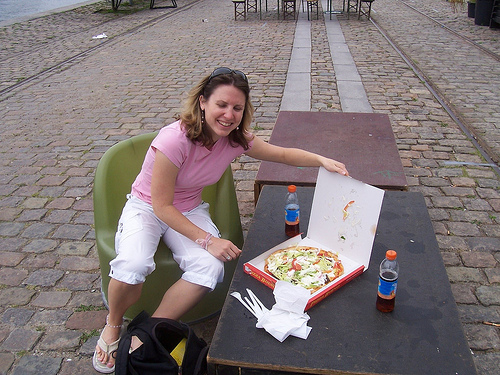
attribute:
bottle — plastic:
[371, 248, 403, 315]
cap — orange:
[384, 245, 398, 264]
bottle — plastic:
[279, 178, 304, 235]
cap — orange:
[281, 182, 298, 196]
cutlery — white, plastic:
[228, 283, 272, 326]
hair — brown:
[175, 61, 260, 150]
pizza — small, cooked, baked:
[265, 246, 341, 291]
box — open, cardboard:
[253, 160, 389, 302]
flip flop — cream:
[80, 319, 125, 372]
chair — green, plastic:
[83, 124, 243, 322]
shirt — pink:
[133, 126, 254, 212]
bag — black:
[121, 312, 204, 368]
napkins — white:
[261, 277, 318, 350]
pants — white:
[111, 198, 225, 285]